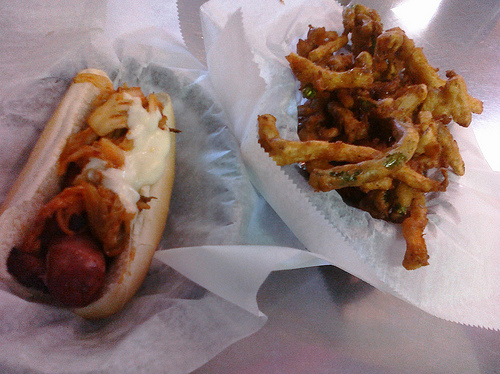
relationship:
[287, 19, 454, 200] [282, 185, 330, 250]
food in paper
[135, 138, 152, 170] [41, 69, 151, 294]
sauce on a hot dog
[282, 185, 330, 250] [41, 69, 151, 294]
paper under hot dog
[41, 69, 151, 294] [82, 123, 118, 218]
hot dog with toppings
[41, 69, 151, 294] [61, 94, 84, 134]
hot dog in a bun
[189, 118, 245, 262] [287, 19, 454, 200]
tray of food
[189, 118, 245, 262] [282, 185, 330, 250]
tray under paper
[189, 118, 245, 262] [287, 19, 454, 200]
tray under food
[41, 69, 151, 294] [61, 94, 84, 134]
hot dog and bun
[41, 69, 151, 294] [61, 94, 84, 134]
hot dog in bun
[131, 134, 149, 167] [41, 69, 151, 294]
cheese on hot dog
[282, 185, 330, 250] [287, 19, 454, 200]
paper holding food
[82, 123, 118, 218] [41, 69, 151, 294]
toppings on hot dog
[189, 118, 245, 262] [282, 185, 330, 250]
dish holding paper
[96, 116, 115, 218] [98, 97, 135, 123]
condiments on food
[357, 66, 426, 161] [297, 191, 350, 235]
fried side dish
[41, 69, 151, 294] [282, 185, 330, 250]
hot dog on paper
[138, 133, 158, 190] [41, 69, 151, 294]
mayonnaise over a hot dog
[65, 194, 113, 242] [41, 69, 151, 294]
onions on hot dog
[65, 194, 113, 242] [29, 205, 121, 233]
onions with red sauce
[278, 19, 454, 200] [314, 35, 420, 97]
food a bunch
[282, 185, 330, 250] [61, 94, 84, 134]
paper underneath bun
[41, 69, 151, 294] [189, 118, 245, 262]
hot dog on a basket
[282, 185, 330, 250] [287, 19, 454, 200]
paper under food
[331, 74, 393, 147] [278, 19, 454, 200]
vegetable on food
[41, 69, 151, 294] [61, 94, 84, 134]
hot dog on a bun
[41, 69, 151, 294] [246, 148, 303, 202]
hot dog in a basket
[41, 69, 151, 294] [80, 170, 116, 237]
hot dog with fixings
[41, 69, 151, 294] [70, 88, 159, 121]
hot dog ready to eat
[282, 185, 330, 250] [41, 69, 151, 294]
paper beneath hot dog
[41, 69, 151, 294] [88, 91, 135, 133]
hot dog has food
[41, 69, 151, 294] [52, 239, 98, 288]
hot dog has been cooked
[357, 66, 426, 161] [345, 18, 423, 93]
fried side asparagus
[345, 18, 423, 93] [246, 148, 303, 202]
asparagus in a basket